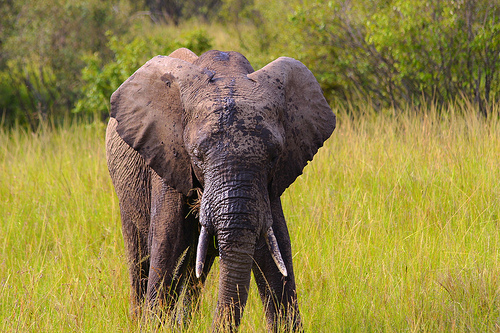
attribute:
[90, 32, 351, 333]
elephant — baby, dark, old, male, standing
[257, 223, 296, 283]
horn — white, short, black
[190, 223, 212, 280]
horn — white, short, black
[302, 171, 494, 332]
grass — green, very tall, brown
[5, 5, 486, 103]
trees — green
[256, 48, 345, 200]
ear — long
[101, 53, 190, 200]
ear — long, large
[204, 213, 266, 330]
trunk — blackened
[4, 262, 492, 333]
grass — tall, lime green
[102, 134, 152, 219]
body — sagging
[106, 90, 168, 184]
edges — darker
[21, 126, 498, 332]
field — grass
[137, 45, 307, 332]
skin — water splashed, wet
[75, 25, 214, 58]
leaves — green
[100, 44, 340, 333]
skin — wrinkled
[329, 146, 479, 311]
grass — tall